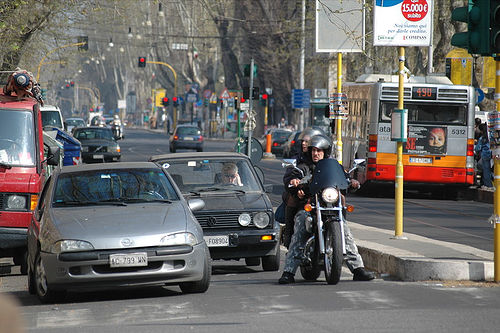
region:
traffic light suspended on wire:
[134, 55, 149, 76]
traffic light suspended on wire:
[160, 98, 167, 109]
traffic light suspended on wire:
[171, 93, 185, 113]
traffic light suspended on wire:
[238, 93, 247, 108]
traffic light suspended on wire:
[260, 93, 269, 107]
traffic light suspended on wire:
[70, 80, 76, 87]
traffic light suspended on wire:
[64, 82, 68, 90]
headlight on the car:
[241, 215, 252, 227]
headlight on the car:
[257, 213, 272, 230]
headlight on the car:
[162, 232, 198, 253]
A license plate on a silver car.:
[108, 252, 150, 269]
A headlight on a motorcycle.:
[323, 188, 338, 203]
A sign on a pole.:
[373, 0, 433, 46]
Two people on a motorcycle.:
[276, 127, 375, 282]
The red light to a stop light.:
[138, 55, 146, 66]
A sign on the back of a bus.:
[402, 122, 447, 156]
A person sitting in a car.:
[221, 162, 242, 187]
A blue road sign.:
[291, 87, 312, 107]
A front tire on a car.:
[31, 250, 66, 302]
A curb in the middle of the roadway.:
[344, 215, 494, 283]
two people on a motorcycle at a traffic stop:
[285, 122, 365, 291]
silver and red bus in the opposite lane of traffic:
[329, 80, 477, 192]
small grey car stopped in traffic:
[28, 163, 214, 298]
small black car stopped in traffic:
[160, 148, 280, 264]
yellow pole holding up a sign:
[372, 0, 432, 249]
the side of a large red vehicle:
[2, 71, 49, 271]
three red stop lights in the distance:
[130, 51, 186, 113]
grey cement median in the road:
[357, 222, 494, 289]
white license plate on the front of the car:
[108, 246, 155, 272]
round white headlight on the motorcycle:
[320, 185, 341, 205]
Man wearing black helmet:
[275, 133, 373, 278]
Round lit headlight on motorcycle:
[321, 188, 340, 203]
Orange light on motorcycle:
[301, 200, 313, 214]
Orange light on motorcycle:
[345, 203, 355, 212]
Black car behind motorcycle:
[145, 147, 280, 272]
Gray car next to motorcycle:
[24, 161, 214, 293]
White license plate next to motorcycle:
[108, 250, 148, 268]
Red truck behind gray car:
[0, 63, 63, 272]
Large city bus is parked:
[330, 70, 477, 193]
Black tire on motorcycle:
[325, 218, 344, 287]